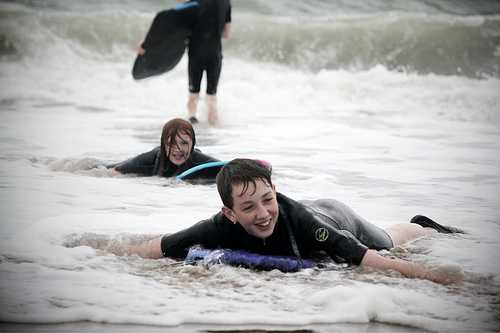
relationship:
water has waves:
[262, 66, 475, 165] [245, 8, 494, 81]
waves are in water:
[245, 8, 494, 81] [262, 66, 475, 165]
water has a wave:
[262, 66, 475, 165] [0, 10, 128, 67]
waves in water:
[245, 8, 494, 81] [262, 66, 475, 165]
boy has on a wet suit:
[145, 161, 466, 283] [277, 193, 388, 258]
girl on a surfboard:
[107, 117, 195, 179] [179, 161, 218, 180]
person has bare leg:
[182, 0, 232, 126] [207, 93, 217, 126]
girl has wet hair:
[107, 117, 195, 179] [163, 117, 194, 146]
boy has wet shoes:
[145, 161, 466, 283] [410, 215, 457, 234]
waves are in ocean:
[245, 8, 494, 81] [2, 33, 116, 203]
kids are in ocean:
[114, 1, 457, 285] [2, 33, 116, 203]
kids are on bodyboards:
[114, 1, 457, 285] [134, 5, 191, 80]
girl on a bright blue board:
[107, 117, 195, 179] [179, 161, 218, 180]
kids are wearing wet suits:
[114, 1, 457, 285] [190, 0, 221, 93]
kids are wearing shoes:
[114, 1, 457, 285] [189, 116, 198, 122]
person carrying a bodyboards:
[182, 0, 232, 126] [134, 5, 191, 80]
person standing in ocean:
[182, 0, 232, 126] [2, 33, 116, 203]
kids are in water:
[114, 1, 457, 285] [262, 66, 475, 165]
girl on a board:
[107, 117, 195, 179] [179, 161, 218, 180]